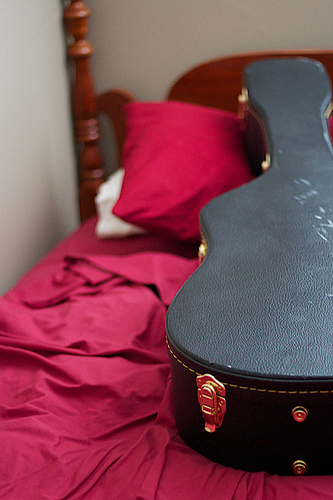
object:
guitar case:
[165, 58, 333, 477]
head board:
[93, 51, 333, 180]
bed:
[1, 49, 332, 496]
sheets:
[0, 214, 333, 498]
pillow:
[111, 99, 255, 245]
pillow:
[92, 167, 149, 238]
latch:
[195, 241, 207, 260]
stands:
[288, 404, 311, 422]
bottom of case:
[165, 327, 332, 478]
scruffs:
[310, 207, 331, 239]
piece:
[237, 88, 250, 118]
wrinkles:
[0, 337, 152, 358]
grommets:
[195, 370, 228, 433]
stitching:
[165, 332, 332, 394]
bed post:
[63, 1, 106, 228]